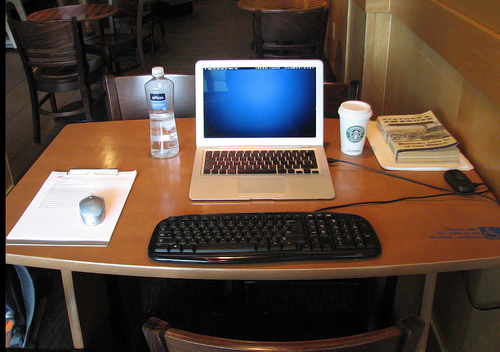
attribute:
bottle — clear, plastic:
[145, 64, 181, 160]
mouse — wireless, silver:
[78, 194, 108, 223]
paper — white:
[9, 170, 144, 242]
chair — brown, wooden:
[145, 317, 426, 352]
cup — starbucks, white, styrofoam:
[337, 99, 375, 155]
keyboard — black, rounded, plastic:
[148, 210, 381, 261]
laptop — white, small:
[189, 60, 333, 199]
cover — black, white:
[383, 110, 451, 145]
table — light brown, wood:
[1, 115, 500, 281]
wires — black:
[320, 156, 495, 212]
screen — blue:
[204, 71, 318, 138]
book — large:
[378, 111, 460, 162]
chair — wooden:
[6, 11, 104, 148]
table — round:
[231, 2, 332, 16]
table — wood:
[27, 3, 123, 22]